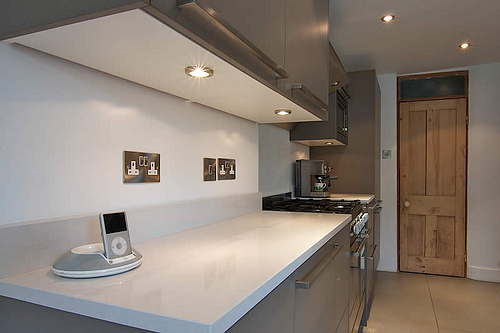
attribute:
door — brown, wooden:
[387, 90, 479, 292]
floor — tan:
[360, 272, 499, 331]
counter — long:
[118, 199, 420, 330]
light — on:
[162, 50, 396, 147]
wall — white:
[1, 43, 315, 226]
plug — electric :
[114, 143, 185, 186]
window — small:
[396, 71, 463, 96]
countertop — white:
[164, 227, 350, 296]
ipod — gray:
[101, 204, 136, 257]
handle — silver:
[294, 240, 346, 290]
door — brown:
[408, 113, 473, 267]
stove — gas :
[261, 187, 366, 246]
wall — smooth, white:
[16, 41, 281, 215]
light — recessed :
[380, 12, 394, 22]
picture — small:
[122, 150, 160, 182]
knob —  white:
[402, 200, 414, 214]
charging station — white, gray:
[48, 238, 147, 278]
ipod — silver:
[99, 210, 136, 261]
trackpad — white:
[51, 241, 146, 277]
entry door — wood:
[395, 94, 469, 277]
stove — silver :
[263, 189, 378, 331]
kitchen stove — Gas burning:
[262, 182, 380, 233]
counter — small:
[287, 181, 379, 206]